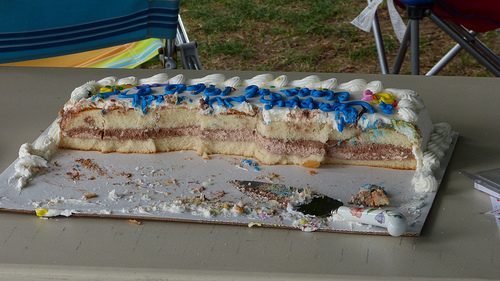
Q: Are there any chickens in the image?
A: No, there are no chickens.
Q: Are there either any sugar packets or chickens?
A: No, there are no chickens or sugar packets.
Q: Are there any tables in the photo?
A: Yes, there is a table.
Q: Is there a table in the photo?
A: Yes, there is a table.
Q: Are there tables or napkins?
A: Yes, there is a table.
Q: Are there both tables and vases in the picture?
A: No, there is a table but no vases.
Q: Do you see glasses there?
A: No, there are no glasses.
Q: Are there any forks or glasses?
A: No, there are no glasses or forks.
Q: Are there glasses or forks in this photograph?
A: No, there are no glasses or forks.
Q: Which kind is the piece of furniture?
A: The piece of furniture is a table.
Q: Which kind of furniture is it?
A: The piece of furniture is a table.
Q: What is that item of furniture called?
A: This is a table.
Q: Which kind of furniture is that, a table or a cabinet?
A: This is a table.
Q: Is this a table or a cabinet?
A: This is a table.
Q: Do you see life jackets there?
A: No, there are no life jackets.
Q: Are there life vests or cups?
A: No, there are no life vests or cups.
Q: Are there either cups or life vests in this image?
A: No, there are no life vests or cups.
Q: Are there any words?
A: Yes, there are words.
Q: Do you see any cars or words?
A: Yes, there are words.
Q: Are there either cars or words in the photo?
A: Yes, there are words.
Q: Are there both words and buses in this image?
A: No, there are words but no buses.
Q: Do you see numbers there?
A: No, there are no numbers.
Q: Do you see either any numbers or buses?
A: No, there are no numbers or buses.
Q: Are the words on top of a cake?
A: Yes, the words are on top of a cake.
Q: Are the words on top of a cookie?
A: No, the words are on top of a cake.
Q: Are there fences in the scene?
A: No, there are no fences.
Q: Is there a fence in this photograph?
A: No, there are no fences.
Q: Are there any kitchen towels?
A: No, there are no kitchen towels.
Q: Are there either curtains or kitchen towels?
A: No, there are no kitchen towels or curtains.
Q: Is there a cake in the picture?
A: Yes, there is a cake.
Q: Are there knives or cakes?
A: Yes, there is a cake.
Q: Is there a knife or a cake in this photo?
A: Yes, there is a cake.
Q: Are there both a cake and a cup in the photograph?
A: No, there is a cake but no cups.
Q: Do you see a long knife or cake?
A: Yes, there is a long cake.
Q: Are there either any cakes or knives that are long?
A: Yes, the cake is long.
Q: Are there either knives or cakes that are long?
A: Yes, the cake is long.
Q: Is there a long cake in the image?
A: Yes, there is a long cake.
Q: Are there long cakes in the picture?
A: Yes, there is a long cake.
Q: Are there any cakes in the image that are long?
A: Yes, there is a cake that is long.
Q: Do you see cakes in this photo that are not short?
A: Yes, there is a long cake.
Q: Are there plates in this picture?
A: No, there are no plates.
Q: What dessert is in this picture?
A: The dessert is a cake.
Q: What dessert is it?
A: The dessert is a cake.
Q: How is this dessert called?
A: This is a cake.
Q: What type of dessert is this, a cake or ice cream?
A: This is a cake.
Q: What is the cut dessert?
A: The dessert is a cake.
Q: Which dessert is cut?
A: The dessert is a cake.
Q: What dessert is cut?
A: The dessert is a cake.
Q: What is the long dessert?
A: The dessert is a cake.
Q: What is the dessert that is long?
A: The dessert is a cake.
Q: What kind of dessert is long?
A: The dessert is a cake.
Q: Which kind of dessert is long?
A: The dessert is a cake.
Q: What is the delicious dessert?
A: The dessert is a cake.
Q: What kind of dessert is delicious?
A: The dessert is a cake.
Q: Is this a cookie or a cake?
A: This is a cake.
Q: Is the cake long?
A: Yes, the cake is long.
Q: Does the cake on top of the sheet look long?
A: Yes, the cake is long.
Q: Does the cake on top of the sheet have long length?
A: Yes, the cake is long.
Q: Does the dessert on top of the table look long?
A: Yes, the cake is long.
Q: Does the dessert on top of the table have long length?
A: Yes, the cake is long.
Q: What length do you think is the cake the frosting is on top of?
A: The cake is long.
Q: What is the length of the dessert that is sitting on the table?
A: The cake is long.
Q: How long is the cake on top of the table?
A: The cake is long.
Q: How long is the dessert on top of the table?
A: The cake is long.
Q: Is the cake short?
A: No, the cake is long.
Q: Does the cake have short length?
A: No, the cake is long.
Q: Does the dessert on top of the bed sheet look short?
A: No, the cake is long.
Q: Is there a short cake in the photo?
A: No, there is a cake but it is long.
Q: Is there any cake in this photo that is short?
A: No, there is a cake but it is long.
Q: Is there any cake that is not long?
A: No, there is a cake but it is long.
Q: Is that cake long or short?
A: The cake is long.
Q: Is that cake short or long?
A: The cake is long.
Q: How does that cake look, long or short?
A: The cake is long.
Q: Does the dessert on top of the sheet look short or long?
A: The cake is long.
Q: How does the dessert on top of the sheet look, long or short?
A: The cake is long.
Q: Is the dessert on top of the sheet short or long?
A: The cake is long.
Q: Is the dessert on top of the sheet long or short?
A: The cake is long.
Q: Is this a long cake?
A: Yes, this is a long cake.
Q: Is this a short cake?
A: No, this is a long cake.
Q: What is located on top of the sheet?
A: The cake is on top of the sheet.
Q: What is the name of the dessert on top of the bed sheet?
A: The dessert is a cake.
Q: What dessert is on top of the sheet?
A: The dessert is a cake.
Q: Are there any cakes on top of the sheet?
A: Yes, there is a cake on top of the sheet.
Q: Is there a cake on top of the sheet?
A: Yes, there is a cake on top of the sheet.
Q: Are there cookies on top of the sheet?
A: No, there is a cake on top of the sheet.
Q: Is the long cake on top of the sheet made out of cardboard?
A: Yes, the cake is on top of the sheet.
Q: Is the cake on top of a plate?
A: No, the cake is on top of the sheet.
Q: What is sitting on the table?
A: The cake is sitting on the table.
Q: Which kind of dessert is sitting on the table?
A: The dessert is a cake.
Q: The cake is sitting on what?
A: The cake is sitting on the table.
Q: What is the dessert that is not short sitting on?
A: The cake is sitting on the table.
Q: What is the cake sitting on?
A: The cake is sitting on the table.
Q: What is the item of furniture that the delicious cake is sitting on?
A: The piece of furniture is a table.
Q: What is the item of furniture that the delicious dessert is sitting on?
A: The piece of furniture is a table.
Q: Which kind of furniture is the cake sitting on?
A: The cake is sitting on the table.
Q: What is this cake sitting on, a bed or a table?
A: The cake is sitting on a table.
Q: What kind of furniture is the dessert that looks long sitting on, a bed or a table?
A: The cake is sitting on a table.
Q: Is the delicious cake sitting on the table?
A: Yes, the cake is sitting on the table.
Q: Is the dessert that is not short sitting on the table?
A: Yes, the cake is sitting on the table.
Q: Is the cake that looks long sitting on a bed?
A: No, the cake is sitting on the table.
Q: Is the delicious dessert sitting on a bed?
A: No, the cake is sitting on the table.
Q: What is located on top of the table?
A: The cake is on top of the table.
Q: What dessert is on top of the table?
A: The dessert is a cake.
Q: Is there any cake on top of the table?
A: Yes, there is a cake on top of the table.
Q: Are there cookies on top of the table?
A: No, there is a cake on top of the table.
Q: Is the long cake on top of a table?
A: Yes, the cake is on top of a table.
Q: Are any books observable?
A: No, there are no books.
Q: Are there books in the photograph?
A: No, there are no books.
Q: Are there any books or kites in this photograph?
A: No, there are no books or kites.